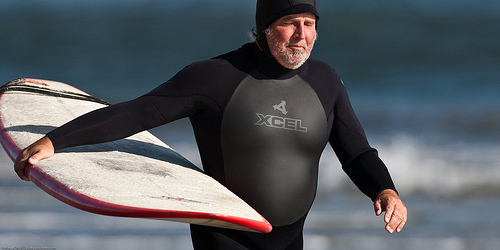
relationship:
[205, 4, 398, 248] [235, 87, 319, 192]
man in suit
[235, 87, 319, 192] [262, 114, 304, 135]
suit says xcel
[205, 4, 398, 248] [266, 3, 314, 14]
man wearing cap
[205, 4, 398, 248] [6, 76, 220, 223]
man carrying surfboard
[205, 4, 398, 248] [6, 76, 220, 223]
man holding surfboard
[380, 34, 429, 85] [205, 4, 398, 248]
sea behind man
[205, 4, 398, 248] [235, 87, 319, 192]
man wearing suit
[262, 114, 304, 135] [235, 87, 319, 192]
xcel on suit